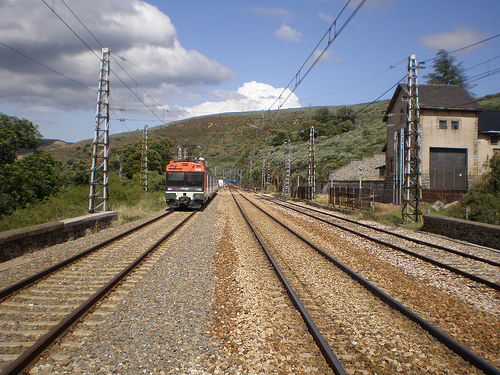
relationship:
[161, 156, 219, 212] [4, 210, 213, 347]
train on tracks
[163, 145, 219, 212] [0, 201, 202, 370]
train on tracks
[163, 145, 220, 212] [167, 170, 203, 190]
train engine has windshield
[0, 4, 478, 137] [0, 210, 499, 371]
wire over train tracks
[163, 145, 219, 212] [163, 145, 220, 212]
train has front portion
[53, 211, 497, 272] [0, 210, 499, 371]
curb along rail roads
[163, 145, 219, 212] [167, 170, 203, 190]
train has windows